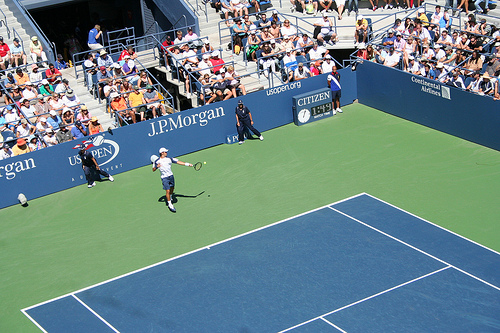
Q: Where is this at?
A: Tennis court.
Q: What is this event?
A: Tennis match.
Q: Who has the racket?
A: The tennis player.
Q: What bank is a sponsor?
A: JP Morgan.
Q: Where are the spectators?
A: In the stands.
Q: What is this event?
A: US Open.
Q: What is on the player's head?
A: Hat.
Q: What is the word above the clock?
A: Citizen.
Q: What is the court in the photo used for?
A: Tennis matches.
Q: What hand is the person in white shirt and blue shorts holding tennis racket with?
A: Left.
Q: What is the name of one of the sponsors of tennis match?
A: J.p. morgan.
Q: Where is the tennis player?
A: Tennis court.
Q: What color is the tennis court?
A: Blue and green.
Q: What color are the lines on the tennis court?
A: White.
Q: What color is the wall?
A: Blue.